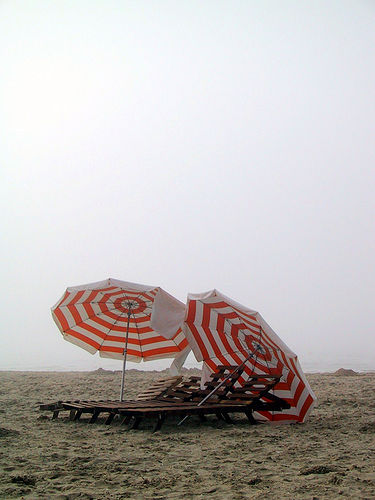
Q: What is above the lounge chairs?
A: Umbrellas.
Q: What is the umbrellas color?
A: Red and white.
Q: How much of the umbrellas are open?
A: Two.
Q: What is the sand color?
A: Grey.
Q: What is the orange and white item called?
A: Umbrella.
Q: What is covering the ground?
A: Sand.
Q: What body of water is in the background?
A: Ocean.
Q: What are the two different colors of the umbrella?
A: Orange and white.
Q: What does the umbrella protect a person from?
A: Sun.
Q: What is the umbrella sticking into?
A: The ground.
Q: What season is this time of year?
A: Summer.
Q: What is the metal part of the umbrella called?
A: Pole.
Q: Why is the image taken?
A: Remembrance.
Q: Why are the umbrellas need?
A: To cover.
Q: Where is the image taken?
A: Side of the beach.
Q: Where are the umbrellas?
A: Sand.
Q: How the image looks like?
A: Good.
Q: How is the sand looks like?
A: Wet.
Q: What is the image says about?
A: Beach with umbrellas.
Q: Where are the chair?
A: On the beach.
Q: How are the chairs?
A: Chairs are wooden.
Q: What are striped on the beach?
A: The umbrellas.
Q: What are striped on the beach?
A: The red and white umbrellas.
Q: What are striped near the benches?
A: The umbrellas.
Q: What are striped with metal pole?
A: The umbrellas.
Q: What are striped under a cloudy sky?
A: The umbrellas.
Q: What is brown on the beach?
A: The benches are.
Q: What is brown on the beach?
A: The beaches are brown.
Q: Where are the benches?
A: Under the umbrellas.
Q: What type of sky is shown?
A: Hazy.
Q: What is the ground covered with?
A: Sand.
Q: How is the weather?
A: Sunny.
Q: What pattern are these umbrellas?
A: Striped.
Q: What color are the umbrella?
A: Red and white.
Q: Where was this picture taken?
A: A beach.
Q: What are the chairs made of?
A: Wood.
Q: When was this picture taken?
A: Daytime.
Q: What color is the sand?
A: Brown.